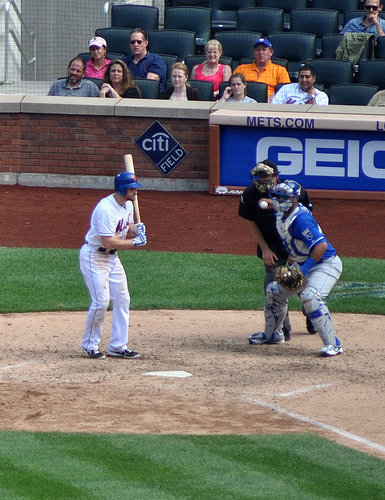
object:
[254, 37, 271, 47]
hat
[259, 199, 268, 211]
ball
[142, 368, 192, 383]
homeplate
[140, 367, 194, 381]
base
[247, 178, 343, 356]
catcher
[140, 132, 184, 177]
citifield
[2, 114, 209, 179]
brick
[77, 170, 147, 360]
batter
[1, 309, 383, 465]
track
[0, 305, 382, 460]
dirt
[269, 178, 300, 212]
helmet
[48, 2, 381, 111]
people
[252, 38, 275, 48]
cap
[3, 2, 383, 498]
photo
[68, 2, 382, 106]
seats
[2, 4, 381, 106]
stadium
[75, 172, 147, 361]
man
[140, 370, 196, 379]
home plate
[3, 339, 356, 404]
baseball diamond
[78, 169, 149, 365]
ball player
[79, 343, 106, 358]
foot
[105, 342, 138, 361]
foot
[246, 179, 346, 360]
baseball catcher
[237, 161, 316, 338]
umpire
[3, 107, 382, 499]
ball game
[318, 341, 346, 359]
foot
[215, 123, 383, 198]
sign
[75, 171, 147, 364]
player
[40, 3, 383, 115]
stands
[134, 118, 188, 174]
sign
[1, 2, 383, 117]
netting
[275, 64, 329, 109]
fans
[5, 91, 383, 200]
wall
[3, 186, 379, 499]
field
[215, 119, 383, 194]
advertisement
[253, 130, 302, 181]
letters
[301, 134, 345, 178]
letters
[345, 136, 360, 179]
letters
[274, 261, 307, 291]
mitt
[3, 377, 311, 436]
mud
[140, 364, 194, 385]
homebase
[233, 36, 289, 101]
man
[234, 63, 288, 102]
shirt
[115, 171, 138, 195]
helmet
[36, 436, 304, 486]
grass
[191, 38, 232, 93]
crowd member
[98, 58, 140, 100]
crowd member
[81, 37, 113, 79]
crowd member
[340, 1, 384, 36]
crowd member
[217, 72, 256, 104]
crowd member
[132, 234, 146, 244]
glove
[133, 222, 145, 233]
glove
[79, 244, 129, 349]
pants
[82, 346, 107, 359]
shoe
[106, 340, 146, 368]
shoe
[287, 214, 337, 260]
jersey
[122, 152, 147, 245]
baseball bat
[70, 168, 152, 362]
person